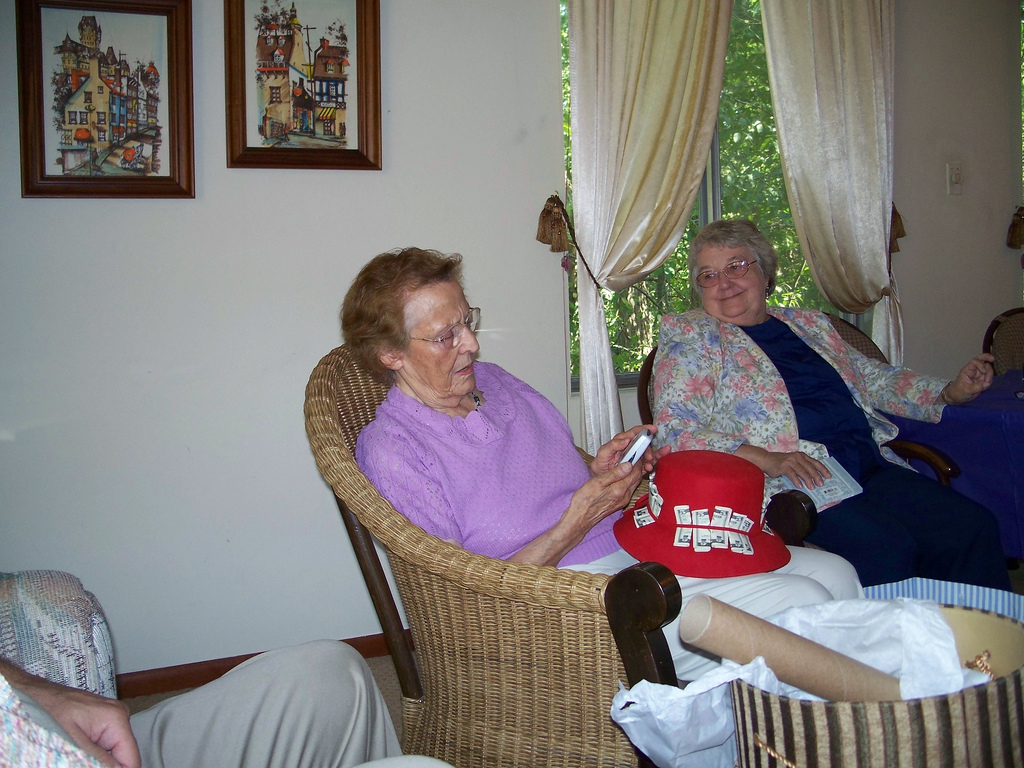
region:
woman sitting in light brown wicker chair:
[301, 246, 864, 766]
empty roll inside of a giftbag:
[675, 588, 1021, 766]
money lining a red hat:
[614, 449, 789, 576]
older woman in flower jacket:
[646, 215, 998, 586]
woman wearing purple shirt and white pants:
[332, 243, 864, 683]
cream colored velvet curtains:
[539, 3, 904, 452]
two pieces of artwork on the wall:
[10, 0, 384, 200]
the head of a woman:
[318, 242, 493, 404]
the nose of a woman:
[444, 330, 489, 360]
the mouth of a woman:
[440, 352, 480, 375]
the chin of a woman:
[446, 365, 482, 400]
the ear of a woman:
[361, 337, 397, 366]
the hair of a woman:
[323, 256, 415, 326]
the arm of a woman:
[510, 472, 591, 572]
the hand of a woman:
[561, 456, 656, 527]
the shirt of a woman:
[368, 384, 587, 537]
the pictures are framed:
[14, 0, 387, 198]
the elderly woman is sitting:
[340, 244, 865, 682]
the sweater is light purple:
[356, 360, 626, 567]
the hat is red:
[612, 448, 790, 576]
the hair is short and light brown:
[340, 241, 462, 388]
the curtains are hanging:
[563, 4, 903, 454]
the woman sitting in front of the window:
[560, 2, 1004, 595]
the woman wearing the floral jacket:
[652, 217, 1001, 594]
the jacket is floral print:
[653, 303, 951, 496]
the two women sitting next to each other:
[339, 214, 995, 677]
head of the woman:
[336, 262, 454, 403]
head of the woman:
[667, 192, 782, 345]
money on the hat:
[731, 530, 760, 562]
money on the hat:
[631, 468, 689, 538]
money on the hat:
[656, 477, 695, 563]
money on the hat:
[680, 505, 716, 566]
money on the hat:
[702, 480, 740, 561]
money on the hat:
[750, 483, 774, 545]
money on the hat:
[693, 519, 758, 558]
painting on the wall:
[228, 0, 372, 156]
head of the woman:
[380, 262, 486, 400]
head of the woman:
[678, 189, 774, 342]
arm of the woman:
[487, 515, 567, 555]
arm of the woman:
[0, 661, 52, 706]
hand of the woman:
[776, 456, 838, 483]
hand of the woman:
[552, 470, 651, 529]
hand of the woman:
[55, 685, 150, 758]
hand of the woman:
[955, 367, 985, 409]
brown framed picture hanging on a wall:
[13, 2, 195, 202]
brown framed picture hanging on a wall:
[218, 3, 392, 177]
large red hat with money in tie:
[606, 450, 796, 577]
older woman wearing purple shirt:
[334, 243, 867, 686]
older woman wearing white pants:
[337, 239, 869, 682]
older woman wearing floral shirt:
[650, 216, 1014, 587]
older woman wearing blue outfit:
[641, 211, 1016, 589]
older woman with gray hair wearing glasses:
[650, 211, 1023, 597]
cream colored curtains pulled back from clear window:
[560, 6, 914, 494]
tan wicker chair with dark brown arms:
[304, 334, 821, 767]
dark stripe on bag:
[745, 683, 762, 766]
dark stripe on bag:
[755, 688, 778, 765]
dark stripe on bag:
[774, 698, 795, 760]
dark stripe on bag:
[796, 693, 816, 766]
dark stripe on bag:
[878, 704, 901, 762]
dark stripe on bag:
[935, 692, 955, 765]